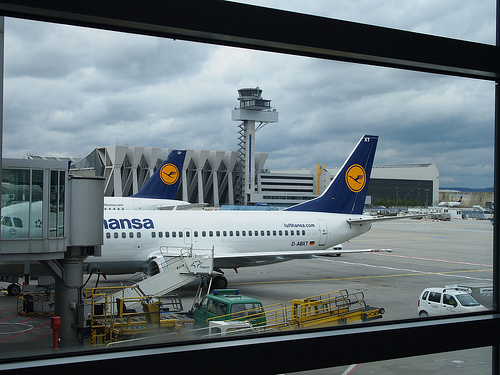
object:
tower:
[231, 86, 278, 203]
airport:
[0, 84, 499, 372]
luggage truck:
[190, 288, 266, 327]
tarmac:
[384, 221, 494, 286]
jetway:
[95, 246, 214, 316]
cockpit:
[0, 201, 41, 235]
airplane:
[0, 149, 209, 236]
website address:
[284, 223, 316, 227]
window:
[151, 231, 157, 239]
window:
[185, 231, 190, 237]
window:
[229, 230, 234, 237]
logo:
[159, 163, 180, 185]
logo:
[345, 163, 367, 193]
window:
[278, 230, 282, 236]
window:
[241, 230, 248, 237]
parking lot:
[184, 276, 500, 339]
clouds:
[0, 2, 500, 162]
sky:
[0, 6, 498, 188]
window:
[301, 229, 306, 236]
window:
[296, 230, 300, 235]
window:
[266, 230, 271, 236]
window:
[222, 230, 228, 237]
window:
[193, 230, 199, 237]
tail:
[130, 148, 187, 198]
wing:
[146, 247, 392, 258]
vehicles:
[397, 207, 409, 211]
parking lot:
[366, 206, 492, 226]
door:
[319, 219, 328, 245]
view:
[3, 9, 500, 375]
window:
[2, 1, 498, 372]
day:
[0, 0, 500, 374]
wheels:
[6, 284, 19, 297]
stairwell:
[235, 121, 250, 206]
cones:
[442, 208, 451, 222]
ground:
[370, 222, 493, 265]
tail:
[282, 134, 380, 214]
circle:
[344, 163, 369, 194]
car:
[415, 286, 489, 319]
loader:
[142, 294, 159, 305]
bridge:
[0, 152, 104, 265]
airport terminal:
[0, 140, 438, 210]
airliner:
[2, 133, 449, 298]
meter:
[49, 315, 63, 350]